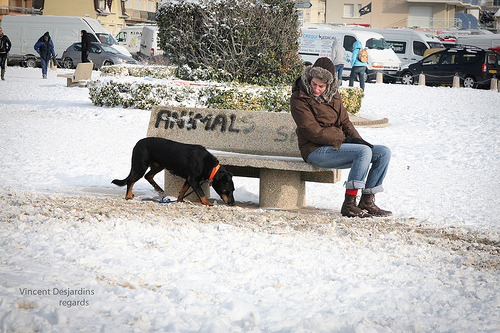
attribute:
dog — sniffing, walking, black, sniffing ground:
[110, 134, 238, 210]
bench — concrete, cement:
[144, 99, 341, 211]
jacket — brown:
[289, 57, 377, 161]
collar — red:
[208, 159, 222, 185]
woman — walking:
[349, 37, 368, 91]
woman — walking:
[329, 39, 347, 86]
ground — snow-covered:
[1, 64, 499, 332]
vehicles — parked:
[6, 10, 500, 88]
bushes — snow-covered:
[89, 68, 364, 115]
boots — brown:
[338, 191, 394, 221]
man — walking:
[35, 29, 58, 79]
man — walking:
[0, 26, 13, 82]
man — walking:
[76, 28, 93, 61]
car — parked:
[62, 41, 140, 72]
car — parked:
[401, 45, 500, 89]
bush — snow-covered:
[155, 0, 305, 87]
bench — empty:
[58, 59, 95, 87]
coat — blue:
[350, 42, 369, 67]